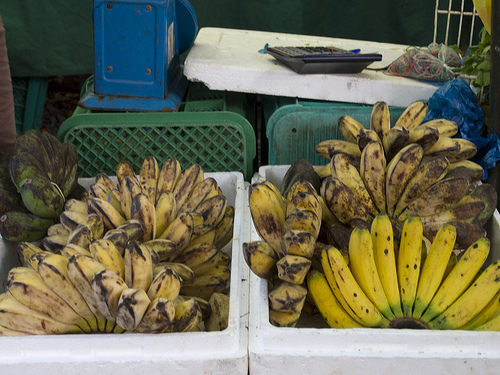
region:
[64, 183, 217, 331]
The bananas are riped.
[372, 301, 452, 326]
Some of the bananas are green at the bottom.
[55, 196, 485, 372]
The bananas are sitting in a white crate.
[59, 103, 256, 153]
The green crates are sitting behind the bananas.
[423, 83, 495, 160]
A blue rag is sitting on the side.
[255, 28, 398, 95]
A calculator on top of the white lid.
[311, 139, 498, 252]
The bananas are brown.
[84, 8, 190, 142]
A blue box is sitting on top of the green crate.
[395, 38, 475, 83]
A pack of rubber bands on top of the white lid.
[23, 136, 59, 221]
The bananas are green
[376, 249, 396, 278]
part of a banana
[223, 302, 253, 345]
part of an edge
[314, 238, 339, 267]
part of a banana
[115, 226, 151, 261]
tip of a banana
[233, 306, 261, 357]
part of a line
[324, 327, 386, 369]
part of an edge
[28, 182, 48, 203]
part of a green banana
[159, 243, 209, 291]
part of a banana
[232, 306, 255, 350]
part of a middle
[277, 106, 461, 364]
The bananas are visible.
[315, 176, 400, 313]
The bananas are visible.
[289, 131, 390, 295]
The bananas are visible.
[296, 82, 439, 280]
The bananas are visible.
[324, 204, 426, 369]
The bananas are visible.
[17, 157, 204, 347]
many bunches of bananas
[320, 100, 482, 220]
bunches of over ripe bananas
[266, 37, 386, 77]
large black calculator on table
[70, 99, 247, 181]
green plastic basket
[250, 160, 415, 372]
bananas in white tub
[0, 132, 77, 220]
green spotty bananas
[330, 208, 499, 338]
bunch of yellow bananas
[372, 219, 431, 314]
yellow bananas with black spots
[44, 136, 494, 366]
two white tubs of bananas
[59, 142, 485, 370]
bananas inside tubs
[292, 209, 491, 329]
the bananas are ripe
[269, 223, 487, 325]
the bananas are yellow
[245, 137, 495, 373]
the fruit is in a white foam box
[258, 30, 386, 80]
this is a black calculator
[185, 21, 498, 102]
the top of the foam box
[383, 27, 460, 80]
a bag of rubber bands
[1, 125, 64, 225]
the bananas are green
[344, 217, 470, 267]
the bananas have spots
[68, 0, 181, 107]
a blue metal box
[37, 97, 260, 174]
a square green crate